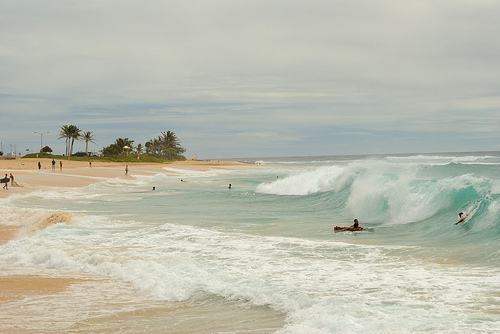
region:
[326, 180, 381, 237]
this is a person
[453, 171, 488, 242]
this is a person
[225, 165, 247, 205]
this is a person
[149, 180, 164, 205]
this is a person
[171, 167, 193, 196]
this is a person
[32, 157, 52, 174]
this is a person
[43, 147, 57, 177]
this is a person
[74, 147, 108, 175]
this is a person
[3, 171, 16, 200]
this is a person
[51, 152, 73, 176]
this is a person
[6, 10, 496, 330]
Exterior view of tropical region.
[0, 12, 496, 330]
Outdoor, beach scene, taken during day.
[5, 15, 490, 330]
Summer-type scene, showing summer water-sport activity.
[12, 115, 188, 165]
Swathe of vegetation, inluding palm trees.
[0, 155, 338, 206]
Figures of people, dotting coastline and water.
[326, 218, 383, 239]
Person, in small boat, near shore.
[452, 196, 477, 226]
Swimmer, riding current to shore.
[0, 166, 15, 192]
Person, carrying surfboard, on beach.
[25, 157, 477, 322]
White surf and white capped, blue water, pounding towards shore.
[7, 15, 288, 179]
Dull blue, cloud-filled sky, above buff-colored sands and vegetation.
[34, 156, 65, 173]
People walking on the beach.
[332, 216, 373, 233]
Someone surfing in the water.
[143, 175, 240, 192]
People swimming in the water.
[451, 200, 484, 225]
Someone riding a wave.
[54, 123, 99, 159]
Palm trees on a beach.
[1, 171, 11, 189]
Someone ready to surf.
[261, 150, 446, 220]
Huge wave headed for shore.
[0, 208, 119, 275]
Water reaching the shore.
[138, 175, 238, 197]
People enjoying the water.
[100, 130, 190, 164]
Landscape on a beach.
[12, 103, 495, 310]
this is a beach area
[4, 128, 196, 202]
these are people on the beach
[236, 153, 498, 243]
this is a big wave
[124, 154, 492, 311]
the water looks turbulent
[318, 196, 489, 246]
two surfers on the wave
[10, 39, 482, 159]
a cloudy sky above the beach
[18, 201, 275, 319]
the tides are strong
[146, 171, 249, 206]
these three people can barely be seen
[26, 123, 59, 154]
a light pole in the background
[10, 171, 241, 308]
a sandy shoreline area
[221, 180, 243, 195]
hed sticking out of the water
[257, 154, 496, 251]
large wave rolling into shore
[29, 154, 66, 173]
people walking along the beach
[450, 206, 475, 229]
person riding a wave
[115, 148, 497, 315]
light blue body of water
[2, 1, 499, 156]
clouds covering the sky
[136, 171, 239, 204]
three people in the water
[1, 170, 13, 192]
person carrying a black board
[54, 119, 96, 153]
palm trees on the shore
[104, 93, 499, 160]
spots of blue sky poking through the clouds